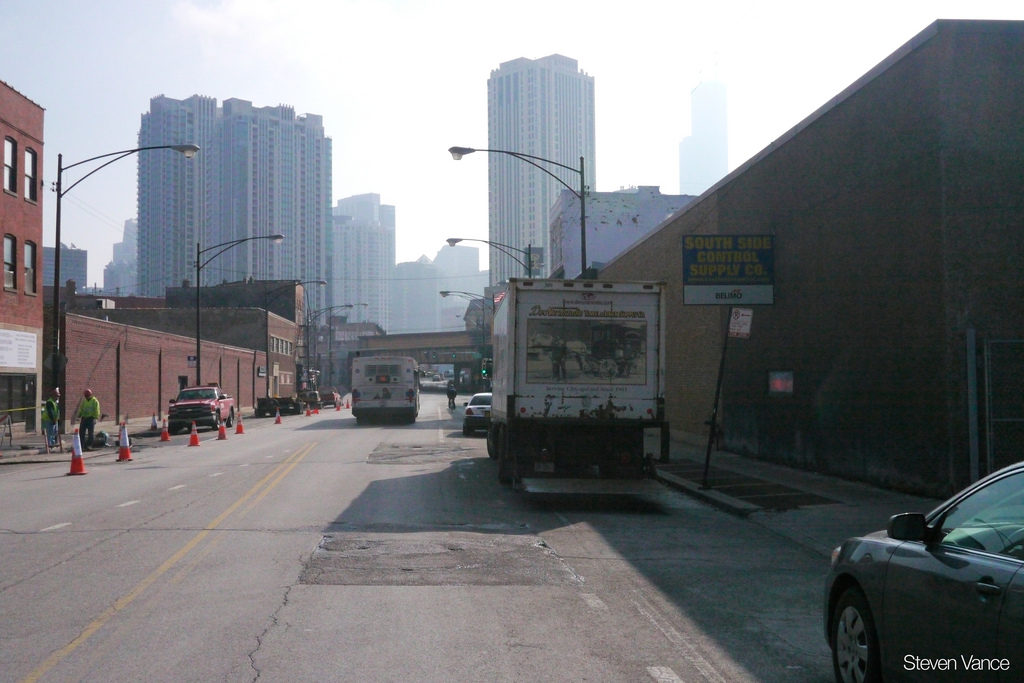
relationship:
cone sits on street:
[65, 428, 89, 476] [0, 381, 835, 671]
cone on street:
[65, 428, 89, 476] [0, 381, 835, 671]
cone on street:
[117, 422, 134, 462] [0, 381, 835, 671]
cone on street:
[153, 407, 180, 446] [0, 381, 835, 671]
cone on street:
[214, 409, 236, 442] [0, 381, 835, 671]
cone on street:
[231, 407, 253, 436] [0, 381, 835, 671]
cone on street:
[270, 404, 283, 424] [0, 381, 835, 671]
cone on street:
[187, 421, 200, 447] [0, 381, 835, 671]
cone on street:
[159, 418, 172, 442] [0, 381, 835, 671]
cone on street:
[108, 419, 141, 463] [0, 381, 835, 671]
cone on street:
[60, 437, 91, 474] [0, 381, 835, 671]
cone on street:
[149, 413, 171, 446] [0, 381, 835, 671]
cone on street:
[186, 415, 204, 452] [0, 381, 835, 671]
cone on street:
[216, 418, 230, 440] [0, 381, 835, 671]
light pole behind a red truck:
[184, 213, 215, 386] [80, 218, 310, 409]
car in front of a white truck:
[443, 386, 480, 423] [432, 287, 675, 646]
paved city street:
[41, 412, 765, 683] [194, 470, 357, 683]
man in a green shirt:
[76, 388, 103, 449] [80, 406, 93, 426]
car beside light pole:
[169, 382, 237, 435] [112, 243, 275, 550]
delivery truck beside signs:
[436, 289, 665, 560] [333, 205, 615, 577]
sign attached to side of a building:
[678, 257, 782, 335] [441, 282, 962, 613]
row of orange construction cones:
[54, 282, 368, 479] [91, 365, 159, 497]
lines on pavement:
[56, 414, 311, 667] [4, 537, 337, 683]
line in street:
[71, 539, 173, 619] [2, 364, 683, 683]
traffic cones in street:
[65, 302, 364, 454] [9, 432, 666, 683]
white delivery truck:
[452, 265, 627, 397] [545, 315, 602, 376]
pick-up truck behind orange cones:
[173, 397, 215, 426] [102, 405, 178, 460]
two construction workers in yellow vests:
[22, 326, 133, 521] [71, 410, 100, 411]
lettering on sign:
[690, 239, 764, 281] [673, 226, 780, 313]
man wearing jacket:
[68, 381, 108, 440] [83, 403, 99, 423]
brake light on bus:
[405, 384, 419, 410] [347, 343, 423, 426]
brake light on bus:
[349, 382, 360, 404] [347, 343, 423, 426]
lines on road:
[24, 441, 320, 681] [1, 390, 833, 680]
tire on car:
[822, 576, 887, 680] [817, 455, 1021, 680]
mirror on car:
[882, 507, 947, 555] [817, 455, 1021, 680]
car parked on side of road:
[169, 377, 243, 432] [1, 390, 833, 680]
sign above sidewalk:
[673, 226, 780, 313] [666, 436, 941, 557]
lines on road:
[561, 579, 661, 681] [306, 575, 449, 677]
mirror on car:
[887, 512, 926, 542] [829, 437, 994, 641]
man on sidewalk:
[76, 388, 103, 449] [21, 409, 65, 489]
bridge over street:
[380, 307, 445, 413] [337, 400, 441, 599]